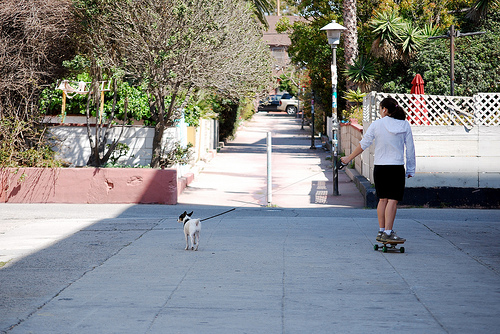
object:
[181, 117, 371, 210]
ground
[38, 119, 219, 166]
building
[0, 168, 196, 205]
yard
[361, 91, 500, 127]
lattice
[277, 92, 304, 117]
car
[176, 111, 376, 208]
alley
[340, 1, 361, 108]
trees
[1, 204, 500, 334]
ground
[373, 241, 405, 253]
skateboard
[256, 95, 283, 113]
car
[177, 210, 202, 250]
dog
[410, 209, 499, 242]
ground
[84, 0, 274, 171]
tree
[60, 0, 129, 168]
tree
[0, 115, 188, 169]
yard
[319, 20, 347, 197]
lamppost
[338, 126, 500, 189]
wall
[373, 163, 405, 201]
shorts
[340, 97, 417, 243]
person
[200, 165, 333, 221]
leash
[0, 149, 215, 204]
brick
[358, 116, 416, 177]
hoodie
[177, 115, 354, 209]
sunlight